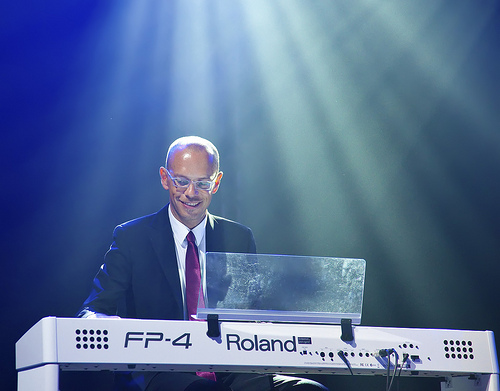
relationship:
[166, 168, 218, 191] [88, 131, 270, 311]
eyeglasses on man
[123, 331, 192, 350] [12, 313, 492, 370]
letters on keyboard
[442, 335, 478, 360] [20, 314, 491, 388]
dots on keyboard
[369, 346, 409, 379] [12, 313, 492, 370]
wires plugged into keyboard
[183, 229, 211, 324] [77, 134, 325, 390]
tie on man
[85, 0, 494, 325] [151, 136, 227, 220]
lights reflecting on head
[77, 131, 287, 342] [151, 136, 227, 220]
man has head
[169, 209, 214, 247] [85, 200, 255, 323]
collar on shirt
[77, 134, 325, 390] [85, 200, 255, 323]
man has shirt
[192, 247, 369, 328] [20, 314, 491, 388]
holder on keyboard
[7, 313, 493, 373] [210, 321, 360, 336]
board has edge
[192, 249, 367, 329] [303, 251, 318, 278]
board has part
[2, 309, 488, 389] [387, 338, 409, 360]
piano has part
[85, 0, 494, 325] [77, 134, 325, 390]
lights shining down on man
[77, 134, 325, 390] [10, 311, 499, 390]
man sitting at table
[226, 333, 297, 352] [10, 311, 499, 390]
word on table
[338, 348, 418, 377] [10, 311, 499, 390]
cords connected to table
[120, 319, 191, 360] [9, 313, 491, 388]
letters on organ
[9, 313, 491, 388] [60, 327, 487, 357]
organ has front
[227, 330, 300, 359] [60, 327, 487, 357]
word on front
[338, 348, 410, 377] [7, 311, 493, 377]
cords connected to organ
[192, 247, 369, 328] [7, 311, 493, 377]
holder on organ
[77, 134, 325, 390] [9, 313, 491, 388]
man playing organ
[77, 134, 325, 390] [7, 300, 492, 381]
man looking down at organ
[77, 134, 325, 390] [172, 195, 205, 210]
man with smile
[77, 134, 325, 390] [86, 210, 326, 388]
man in suit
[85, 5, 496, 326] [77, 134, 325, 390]
lights are shining down on a man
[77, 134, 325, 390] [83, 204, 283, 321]
man wearing suit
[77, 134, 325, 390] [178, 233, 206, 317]
man wearing tie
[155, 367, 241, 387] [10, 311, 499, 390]
cords are connected to table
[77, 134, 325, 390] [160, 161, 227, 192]
man wearing eyeglasses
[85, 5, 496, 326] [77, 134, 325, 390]
lights are shining down on man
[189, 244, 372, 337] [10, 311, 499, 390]
screen on table